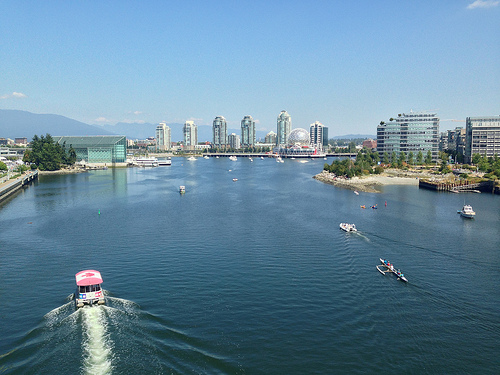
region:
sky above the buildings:
[172, 20, 262, 90]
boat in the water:
[50, 250, 130, 320]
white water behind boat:
[71, 312, 121, 353]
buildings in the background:
[176, 110, 321, 165]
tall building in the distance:
[257, 106, 303, 159]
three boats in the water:
[331, 191, 483, 314]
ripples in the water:
[154, 283, 220, 374]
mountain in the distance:
[25, 99, 87, 130]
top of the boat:
[60, 256, 110, 299]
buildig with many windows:
[371, 103, 456, 166]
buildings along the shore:
[126, 101, 497, 181]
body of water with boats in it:
[162, 226, 319, 357]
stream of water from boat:
[64, 317, 124, 374]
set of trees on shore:
[21, 130, 82, 172]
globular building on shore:
[286, 128, 312, 153]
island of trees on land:
[333, 140, 448, 174]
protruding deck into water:
[421, 170, 496, 195]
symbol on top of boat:
[73, 270, 105, 286]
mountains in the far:
[1, 96, 120, 143]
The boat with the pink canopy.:
[69, 265, 107, 305]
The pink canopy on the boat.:
[72, 268, 103, 287]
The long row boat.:
[380, 255, 412, 287]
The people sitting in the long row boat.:
[382, 255, 404, 280]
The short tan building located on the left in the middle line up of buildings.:
[153, 120, 174, 149]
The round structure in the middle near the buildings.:
[281, 127, 311, 145]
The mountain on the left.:
[2, 102, 105, 136]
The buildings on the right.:
[355, 91, 496, 164]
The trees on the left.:
[16, 125, 72, 170]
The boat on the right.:
[455, 199, 481, 220]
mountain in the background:
[13, 97, 92, 137]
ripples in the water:
[136, 307, 202, 374]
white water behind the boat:
[76, 303, 118, 369]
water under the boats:
[190, 214, 295, 286]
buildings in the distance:
[146, 100, 314, 175]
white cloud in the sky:
[3, 80, 38, 113]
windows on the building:
[386, 123, 436, 158]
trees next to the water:
[331, 153, 380, 182]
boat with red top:
[61, 256, 121, 303]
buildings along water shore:
[155, 119, 343, 155]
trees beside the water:
[24, 140, 81, 167]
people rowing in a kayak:
[367, 250, 412, 294]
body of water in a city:
[2, 189, 489, 371]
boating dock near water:
[413, 174, 495, 189]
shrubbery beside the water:
[333, 147, 498, 185]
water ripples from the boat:
[0, 308, 231, 374]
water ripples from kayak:
[416, 287, 493, 327]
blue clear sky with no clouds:
[3, 1, 498, 106]